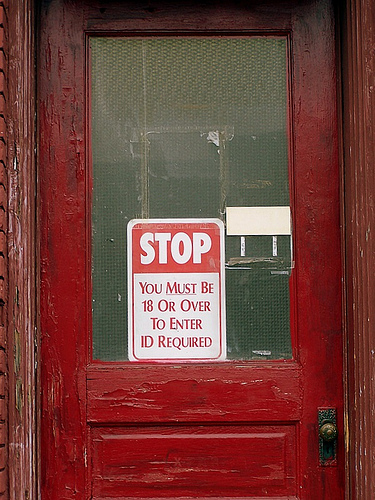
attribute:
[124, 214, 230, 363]
sign — white, red, prohibiting, letting, written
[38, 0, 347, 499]
door — wooden, red, worn, painted, old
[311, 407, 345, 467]
door knob — metal, round, old fashioned, brass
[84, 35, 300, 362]
pane — glass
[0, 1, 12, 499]
wall — red, brick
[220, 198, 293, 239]
paper — white, plain, pinned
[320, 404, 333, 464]
plate — brass, rectangular, metal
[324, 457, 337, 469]
paint — red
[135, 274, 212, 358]
lettering — red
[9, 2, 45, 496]
door frame — old, brown, painted, wooden, chipped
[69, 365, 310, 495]
panels — wood, cracked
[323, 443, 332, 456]
key hole — key hole, old fashioned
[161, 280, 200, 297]
word — underlined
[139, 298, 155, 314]
number — 18